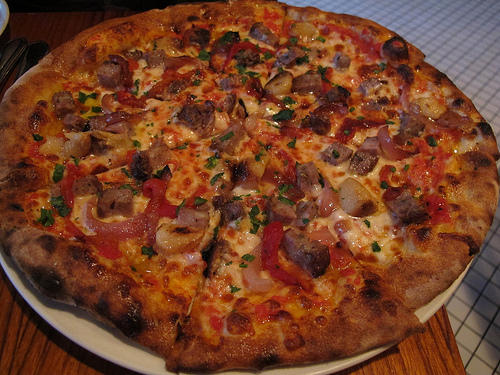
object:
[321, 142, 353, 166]
meat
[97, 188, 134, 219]
meat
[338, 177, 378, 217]
meat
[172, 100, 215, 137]
meat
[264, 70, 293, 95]
meat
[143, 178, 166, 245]
vegetable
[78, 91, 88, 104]
vegetable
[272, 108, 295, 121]
vegetable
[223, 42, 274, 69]
vegetable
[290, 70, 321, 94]
sausage piece5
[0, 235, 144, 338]
brown crust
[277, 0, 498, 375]
tiles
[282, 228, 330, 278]
sausage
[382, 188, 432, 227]
sausage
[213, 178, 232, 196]
sausage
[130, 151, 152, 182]
sausage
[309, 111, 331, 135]
sausage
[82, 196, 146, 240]
vegetable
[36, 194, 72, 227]
vegetable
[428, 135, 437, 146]
vegetable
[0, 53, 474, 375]
plate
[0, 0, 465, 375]
table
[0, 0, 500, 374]
edge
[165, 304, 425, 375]
crust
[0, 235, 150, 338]
burned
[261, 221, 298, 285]
pepper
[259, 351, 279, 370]
burnt crust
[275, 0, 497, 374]
tiled floor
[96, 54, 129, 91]
sausage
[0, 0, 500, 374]
cheese topping